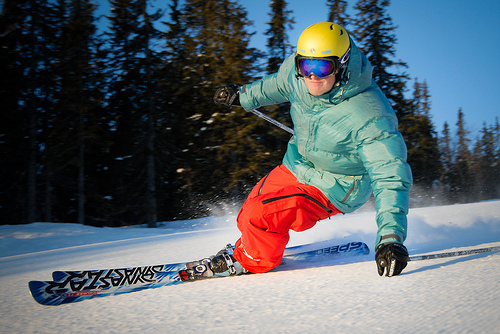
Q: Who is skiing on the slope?
A: The person on the skis.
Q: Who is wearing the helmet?
A: The skier.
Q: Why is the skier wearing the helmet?
A: For safety.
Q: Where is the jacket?
A: On the skier.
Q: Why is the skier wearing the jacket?
A: For warmth.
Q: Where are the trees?
A: Behind the skier.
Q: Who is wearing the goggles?
A: The skier.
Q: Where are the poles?
A: In the skier's hands.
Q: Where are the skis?
A: Under the skier.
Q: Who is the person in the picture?
A: Its a person skiing.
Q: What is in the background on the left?
A: Pine trees on the mountain.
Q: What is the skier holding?
A: A ski pole.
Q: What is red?
A: Pants.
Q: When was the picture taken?
A: Daytime.